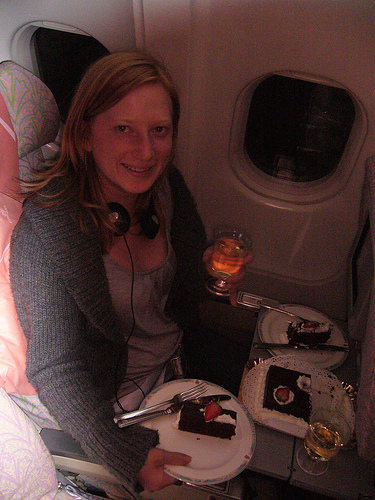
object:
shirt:
[99, 192, 185, 415]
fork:
[113, 380, 210, 424]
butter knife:
[118, 394, 232, 430]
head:
[78, 46, 180, 194]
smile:
[118, 160, 160, 180]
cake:
[172, 398, 238, 440]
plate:
[134, 378, 257, 486]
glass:
[295, 407, 352, 476]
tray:
[231, 301, 364, 500]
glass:
[204, 226, 254, 296]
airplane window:
[29, 26, 111, 124]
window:
[224, 66, 370, 207]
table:
[236, 301, 375, 500]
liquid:
[211, 236, 248, 277]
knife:
[116, 393, 231, 430]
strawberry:
[204, 397, 223, 423]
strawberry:
[275, 386, 290, 403]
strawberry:
[303, 321, 319, 331]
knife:
[236, 290, 305, 323]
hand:
[137, 446, 192, 495]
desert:
[278, 316, 336, 351]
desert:
[262, 363, 312, 427]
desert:
[172, 397, 238, 440]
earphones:
[104, 200, 161, 414]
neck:
[94, 166, 140, 215]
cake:
[260, 364, 313, 429]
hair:
[6, 48, 180, 259]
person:
[8, 51, 255, 500]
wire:
[108, 235, 145, 416]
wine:
[212, 238, 248, 279]